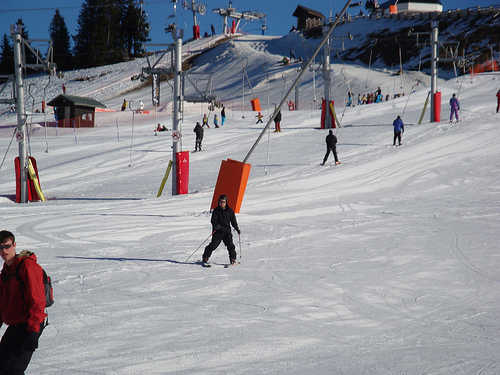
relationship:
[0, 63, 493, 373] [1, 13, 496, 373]
people on slopes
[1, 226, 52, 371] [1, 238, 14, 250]
boy wearing glasses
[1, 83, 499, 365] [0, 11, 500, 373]
people at ski resort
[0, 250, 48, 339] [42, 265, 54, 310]
jacket and backpack